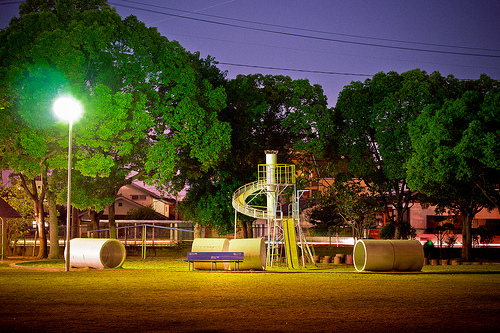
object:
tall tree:
[0, 1, 235, 263]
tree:
[183, 68, 338, 232]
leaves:
[490, 94, 498, 99]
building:
[329, 171, 499, 246]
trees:
[330, 61, 498, 262]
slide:
[229, 150, 326, 267]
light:
[49, 92, 90, 123]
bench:
[181, 244, 249, 272]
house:
[81, 179, 193, 249]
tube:
[350, 236, 427, 279]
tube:
[190, 233, 263, 270]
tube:
[64, 233, 129, 271]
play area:
[2, 212, 498, 332]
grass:
[3, 252, 494, 332]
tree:
[404, 76, 499, 258]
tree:
[332, 66, 467, 240]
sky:
[0, 0, 499, 167]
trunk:
[44, 168, 64, 258]